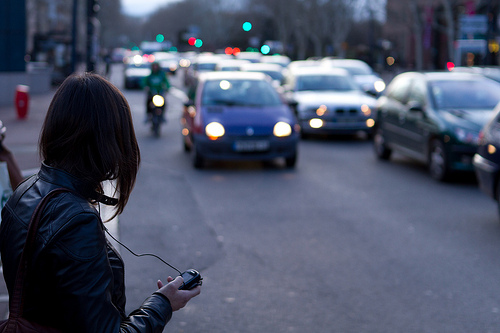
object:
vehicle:
[184, 70, 297, 170]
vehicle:
[284, 64, 371, 134]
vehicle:
[376, 70, 479, 181]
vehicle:
[147, 86, 169, 139]